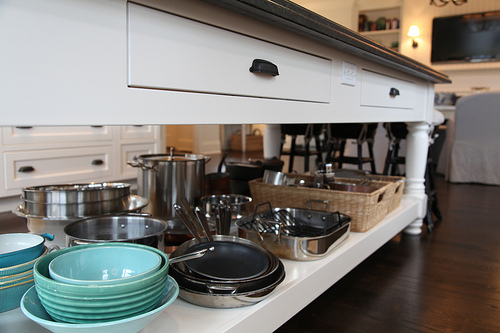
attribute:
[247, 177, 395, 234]
basket — wicker, storage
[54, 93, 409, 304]
shelf — white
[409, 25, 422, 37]
shade — white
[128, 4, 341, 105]
drawer — white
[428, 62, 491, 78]
shelf — black, flat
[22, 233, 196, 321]
bowls — stacked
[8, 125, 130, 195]
drawer — white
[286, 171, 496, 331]
floor — brown, wooden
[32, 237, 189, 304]
bowls — light blue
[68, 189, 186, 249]
pot — silver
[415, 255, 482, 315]
wood flooring — dark brown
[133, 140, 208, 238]
pot — silver, large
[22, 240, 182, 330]
bowls — blue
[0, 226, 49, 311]
bowls — blue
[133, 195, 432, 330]
shelf — white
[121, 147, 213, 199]
pot — stainless steel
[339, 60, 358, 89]
outlet — electrical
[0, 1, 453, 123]
counter top — part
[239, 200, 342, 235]
rack — black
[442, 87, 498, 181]
chair cover — white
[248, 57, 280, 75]
handle — black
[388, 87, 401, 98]
handle — black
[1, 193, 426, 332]
shelf — white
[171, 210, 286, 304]
pans — stacked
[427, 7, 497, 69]
tv — flat screen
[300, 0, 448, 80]
coutertop — gray, granite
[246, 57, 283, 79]
drawer pull — black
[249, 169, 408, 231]
basket — storage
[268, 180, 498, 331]
floor — wooden, brown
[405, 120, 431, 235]
leg — white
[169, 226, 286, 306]
pan stack — silver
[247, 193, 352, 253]
pan — silver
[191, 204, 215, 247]
handle — metal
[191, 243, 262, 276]
coating — non stick, black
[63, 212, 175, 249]
pot — open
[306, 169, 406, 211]
basket — wicker